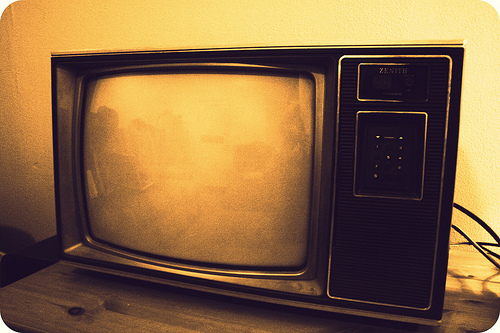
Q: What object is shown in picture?
A: A television.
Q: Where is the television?
A: On a table.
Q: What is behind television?
A: Wall.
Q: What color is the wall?
A: Yellow.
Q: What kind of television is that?
A: Old television.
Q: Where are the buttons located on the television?
A: Left side.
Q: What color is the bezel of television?
A: Black.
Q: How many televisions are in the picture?
A: One.